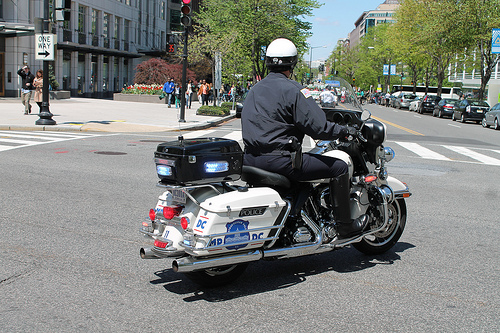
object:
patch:
[300, 88, 311, 98]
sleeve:
[291, 91, 346, 141]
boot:
[335, 214, 369, 238]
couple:
[16, 65, 42, 115]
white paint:
[397, 131, 497, 186]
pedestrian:
[16, 64, 34, 115]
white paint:
[2, 119, 89, 155]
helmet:
[263, 37, 296, 72]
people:
[33, 69, 44, 112]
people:
[163, 78, 174, 107]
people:
[341, 87, 345, 104]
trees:
[244, 0, 279, 90]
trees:
[428, 0, 453, 101]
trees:
[367, 16, 424, 90]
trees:
[355, 38, 378, 84]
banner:
[492, 29, 500, 52]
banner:
[383, 63, 396, 76]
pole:
[180, 4, 188, 120]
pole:
[35, 9, 56, 125]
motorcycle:
[138, 75, 408, 286]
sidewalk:
[0, 95, 217, 132]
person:
[195, 79, 209, 106]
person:
[183, 79, 192, 108]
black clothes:
[236, 72, 351, 154]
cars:
[389, 90, 417, 108]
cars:
[409, 99, 420, 112]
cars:
[415, 94, 441, 114]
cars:
[432, 98, 456, 117]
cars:
[452, 98, 487, 122]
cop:
[241, 36, 369, 238]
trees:
[447, 0, 497, 100]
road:
[0, 87, 495, 333]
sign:
[35, 33, 53, 58]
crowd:
[162, 79, 239, 106]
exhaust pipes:
[140, 241, 331, 272]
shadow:
[153, 238, 365, 313]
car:
[480, 101, 500, 127]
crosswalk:
[0, 130, 98, 151]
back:
[137, 137, 240, 285]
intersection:
[61, 137, 464, 304]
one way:
[37, 36, 51, 48]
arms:
[32, 78, 34, 85]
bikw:
[141, 74, 406, 285]